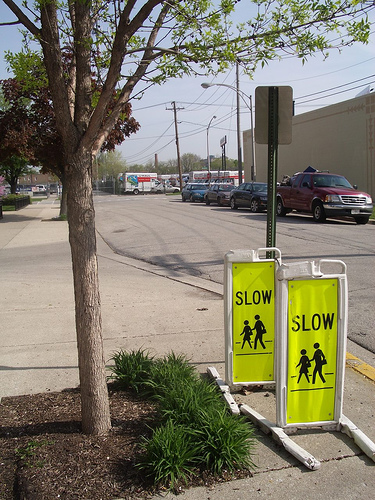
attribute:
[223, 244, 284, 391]
sign — yellow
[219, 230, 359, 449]
sign — yellow and black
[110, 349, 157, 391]
bush — small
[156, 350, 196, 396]
bush — small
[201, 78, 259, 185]
light post — grey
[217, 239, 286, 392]
sign — neon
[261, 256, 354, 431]
sign — neon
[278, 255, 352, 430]
sign — yellow and white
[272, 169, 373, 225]
cars — parked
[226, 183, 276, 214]
cars — parked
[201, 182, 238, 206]
cars — parked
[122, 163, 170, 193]
truck — white, Uhaul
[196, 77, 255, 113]
light — tall, street light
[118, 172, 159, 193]
uhaul van — orange and white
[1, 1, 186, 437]
tree — tall, small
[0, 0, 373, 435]
tree — thin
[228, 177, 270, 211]
car — dark colored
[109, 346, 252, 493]
plants — green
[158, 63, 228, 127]
sky — blue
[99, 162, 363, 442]
street — empty, city street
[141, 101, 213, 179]
poles — wooden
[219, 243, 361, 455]
signs — green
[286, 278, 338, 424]
sign — yellow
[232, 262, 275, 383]
sign — yellow and white, yellow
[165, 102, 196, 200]
pole — long, phone pole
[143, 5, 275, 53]
plants — green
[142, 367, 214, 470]
grass — green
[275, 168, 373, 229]
truck — red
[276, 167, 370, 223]
truck — red